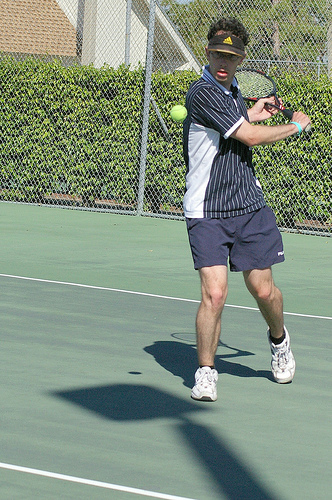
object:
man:
[182, 15, 312, 400]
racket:
[233, 67, 311, 133]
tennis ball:
[169, 103, 188, 124]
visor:
[207, 32, 248, 58]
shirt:
[183, 64, 267, 219]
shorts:
[185, 201, 286, 271]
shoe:
[265, 324, 295, 383]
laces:
[277, 347, 288, 365]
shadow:
[142, 330, 292, 386]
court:
[0, 201, 331, 499]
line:
[0, 270, 331, 325]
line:
[0, 456, 202, 500]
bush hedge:
[0, 53, 331, 224]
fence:
[1, 0, 331, 239]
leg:
[240, 210, 283, 341]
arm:
[193, 84, 299, 147]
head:
[203, 17, 247, 81]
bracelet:
[289, 119, 303, 137]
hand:
[290, 111, 311, 134]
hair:
[206, 17, 251, 45]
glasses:
[208, 50, 240, 62]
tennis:
[169, 68, 310, 133]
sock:
[268, 330, 287, 345]